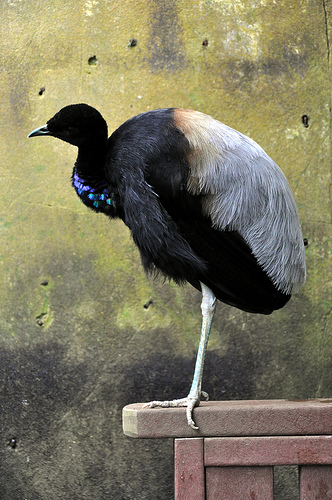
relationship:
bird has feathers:
[26, 100, 311, 424] [170, 102, 309, 298]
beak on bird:
[13, 110, 53, 144] [30, 78, 272, 332]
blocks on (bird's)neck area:
[70, 168, 117, 221] [70, 161, 116, 220]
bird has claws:
[19, 63, 314, 440] [145, 391, 214, 430]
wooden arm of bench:
[116, 398, 328, 439] [121, 397, 327, 497]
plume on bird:
[169, 107, 303, 298] [26, 100, 311, 424]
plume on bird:
[216, 129, 302, 292] [37, 89, 301, 312]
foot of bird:
[143, 383, 219, 432] [26, 100, 311, 424]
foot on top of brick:
[143, 383, 219, 432] [119, 400, 321, 435]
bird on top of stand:
[19, 63, 314, 440] [120, 398, 321, 492]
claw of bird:
[188, 424, 201, 430] [26, 100, 311, 424]